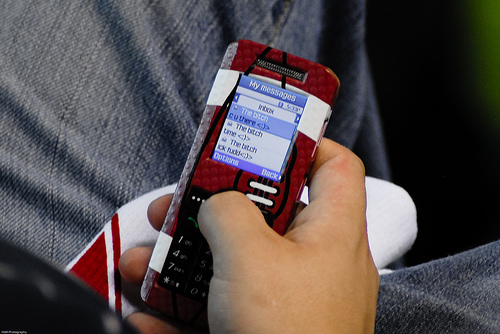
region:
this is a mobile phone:
[133, 35, 348, 332]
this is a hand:
[98, 126, 424, 331]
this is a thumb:
[196, 191, 281, 263]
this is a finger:
[298, 131, 368, 242]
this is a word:
[247, 72, 263, 89]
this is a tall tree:
[261, 81, 300, 101]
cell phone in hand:
[145, 38, 377, 332]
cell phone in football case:
[141, 39, 338, 329]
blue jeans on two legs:
[2, 0, 499, 330]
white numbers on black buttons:
[159, 230, 213, 301]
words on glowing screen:
[210, 70, 304, 182]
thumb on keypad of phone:
[142, 38, 378, 331]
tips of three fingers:
[115, 192, 175, 331]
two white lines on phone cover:
[140, 37, 341, 326]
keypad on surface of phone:
[159, 187, 271, 304]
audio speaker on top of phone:
[140, 37, 342, 329]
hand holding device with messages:
[142, 30, 377, 325]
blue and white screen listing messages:
[205, 66, 305, 181]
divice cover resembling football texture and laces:
[140, 35, 345, 315]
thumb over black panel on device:
[160, 185, 265, 320]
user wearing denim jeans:
[6, 6, 486, 321]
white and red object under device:
[60, 167, 415, 319]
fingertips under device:
[115, 190, 185, 325]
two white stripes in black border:
[240, 175, 275, 205]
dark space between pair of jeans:
[345, 0, 495, 270]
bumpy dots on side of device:
[165, 107, 220, 227]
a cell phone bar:
[154, 18, 353, 332]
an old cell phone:
[171, 45, 310, 277]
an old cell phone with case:
[147, 72, 328, 329]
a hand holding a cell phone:
[146, 75, 372, 325]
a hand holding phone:
[154, 47, 382, 327]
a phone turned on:
[155, 52, 311, 327]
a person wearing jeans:
[18, 34, 240, 201]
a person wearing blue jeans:
[22, 9, 252, 259]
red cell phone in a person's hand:
[136, 40, 341, 332]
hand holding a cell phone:
[104, 120, 383, 332]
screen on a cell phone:
[204, 67, 309, 180]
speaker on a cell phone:
[246, 48, 314, 84]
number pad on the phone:
[160, 235, 216, 301]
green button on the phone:
[179, 209, 201, 231]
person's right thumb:
[195, 183, 271, 251]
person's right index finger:
[297, 128, 374, 234]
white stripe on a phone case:
[202, 60, 334, 145]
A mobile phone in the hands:
[160, 44, 327, 321]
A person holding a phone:
[225, 187, 386, 322]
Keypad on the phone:
[170, 192, 203, 294]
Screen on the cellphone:
[215, 67, 314, 177]